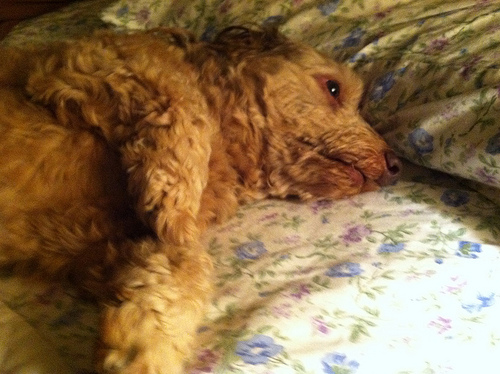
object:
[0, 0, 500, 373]
bed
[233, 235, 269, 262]
floral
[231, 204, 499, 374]
comforter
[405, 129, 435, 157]
flowers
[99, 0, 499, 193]
pillow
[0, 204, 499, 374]
sheet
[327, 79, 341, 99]
eye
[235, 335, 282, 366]
flower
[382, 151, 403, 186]
nose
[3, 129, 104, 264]
belly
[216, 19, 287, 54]
ear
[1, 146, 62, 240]
fur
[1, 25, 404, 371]
dog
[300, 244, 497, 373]
light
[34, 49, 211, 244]
leg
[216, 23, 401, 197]
head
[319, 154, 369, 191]
mouth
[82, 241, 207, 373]
leg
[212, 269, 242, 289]
leaves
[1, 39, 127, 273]
side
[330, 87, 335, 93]
dot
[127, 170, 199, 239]
paw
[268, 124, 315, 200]
fur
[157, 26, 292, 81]
fur